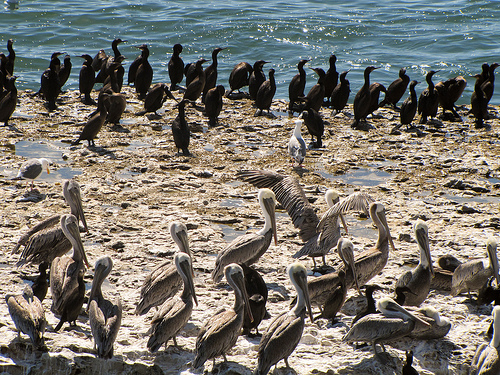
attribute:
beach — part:
[141, 171, 210, 184]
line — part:
[39, 113, 67, 121]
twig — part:
[347, 129, 359, 133]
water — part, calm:
[376, 35, 381, 36]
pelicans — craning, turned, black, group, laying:
[213, 68, 307, 102]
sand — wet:
[111, 137, 123, 145]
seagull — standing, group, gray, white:
[129, 223, 203, 359]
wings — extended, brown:
[249, 165, 366, 223]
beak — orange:
[384, 219, 398, 250]